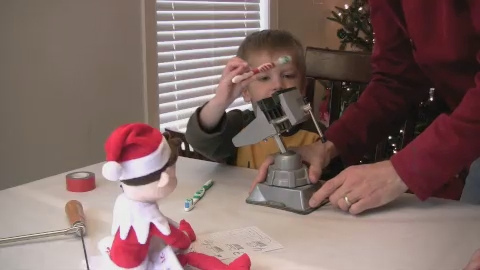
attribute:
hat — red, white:
[101, 121, 173, 181]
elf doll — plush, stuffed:
[101, 121, 251, 269]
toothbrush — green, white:
[184, 178, 214, 212]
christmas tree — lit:
[327, 0, 452, 162]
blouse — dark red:
[319, 2, 480, 202]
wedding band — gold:
[345, 194, 352, 207]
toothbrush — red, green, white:
[232, 54, 291, 85]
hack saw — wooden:
[0, 199, 91, 268]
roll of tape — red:
[66, 171, 97, 193]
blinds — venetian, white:
[156, 0, 261, 130]